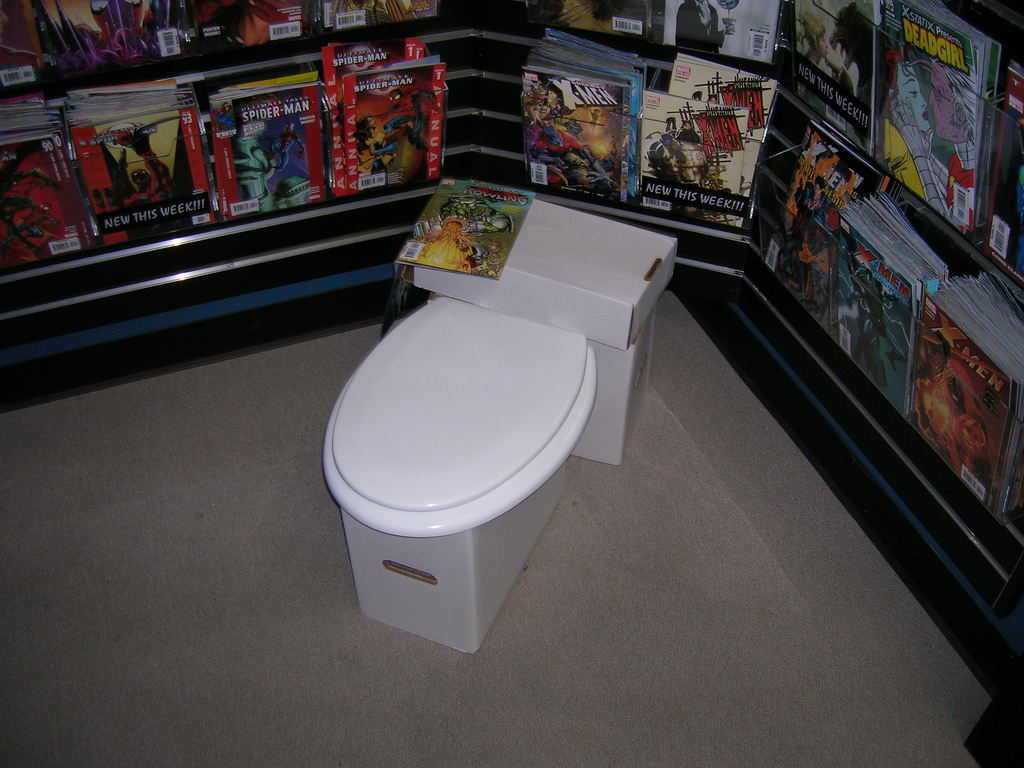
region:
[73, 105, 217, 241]
the colorful comic book on the shelf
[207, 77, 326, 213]
the colorful comic book on the shelf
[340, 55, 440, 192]
the colorful comic book on the shelf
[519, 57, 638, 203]
the colorful comic book on the shelf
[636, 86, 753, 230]
the colorful comic book on the shelf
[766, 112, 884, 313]
the colorful comic book on the shelf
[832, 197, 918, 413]
the colorful comic book on the shelf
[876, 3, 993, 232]
the colorful comic book on the shelf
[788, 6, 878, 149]
the colorful comic book on the shelf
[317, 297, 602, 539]
the toilet seat on the box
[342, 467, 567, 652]
the box under the toilet seat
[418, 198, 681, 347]
the lid of the box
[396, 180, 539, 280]
the magazine on the lid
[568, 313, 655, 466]
the box on the ground acting as the tank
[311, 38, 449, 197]
the spider man magazine behind the toilet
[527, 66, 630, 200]
the x-men magazine behind the lid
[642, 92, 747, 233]
the tan x men magazine behind the lid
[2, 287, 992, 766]
the floor under the boxes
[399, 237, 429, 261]
the white upc on the magazine lid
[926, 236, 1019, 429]
a magazine on the shelf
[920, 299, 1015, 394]
a magazine on the shelf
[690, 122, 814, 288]
a magazine on the shelf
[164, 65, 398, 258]
a magazine on the shelf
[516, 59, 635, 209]
multi colored comic with white lettering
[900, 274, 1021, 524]
orange and black cover to X-MEN comic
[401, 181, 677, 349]
white top of a cardboard box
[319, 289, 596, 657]
white porcelain toilet seat sitting on a box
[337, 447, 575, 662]
white cardboard box with a tan opening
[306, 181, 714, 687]
Makeshift toilet on floor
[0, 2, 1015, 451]
Comic books on wall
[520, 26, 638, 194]
Comics on a shelf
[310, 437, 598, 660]
White box under toilet seat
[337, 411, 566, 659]
Box under toilet seat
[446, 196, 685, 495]
Boxes near the wall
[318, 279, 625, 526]
Toilet seat above box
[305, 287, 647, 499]
White toilet seat above box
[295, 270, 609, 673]
the toilet has a lid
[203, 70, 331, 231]
magazines on display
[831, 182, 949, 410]
books on a pile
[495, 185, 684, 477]
the box is color white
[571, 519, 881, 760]
teh floor is gray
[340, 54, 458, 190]
A comic on a shelf.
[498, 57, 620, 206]
A comic on a shelf.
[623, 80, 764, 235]
A comic on a shelf.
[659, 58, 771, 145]
A comic on a shelf.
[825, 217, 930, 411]
A comic on a shelf.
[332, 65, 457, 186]
A comic on a shelf.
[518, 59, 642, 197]
A comic on a shelf.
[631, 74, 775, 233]
A comic on a shelf.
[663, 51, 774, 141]
A comic on a shelf.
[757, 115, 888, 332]
A comic on a shelf.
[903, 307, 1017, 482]
A comic on a shelf.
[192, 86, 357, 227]
A comic on a shelf.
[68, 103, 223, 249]
A comic on a shelf.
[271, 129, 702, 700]
a toilet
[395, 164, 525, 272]
a comic book on the toilet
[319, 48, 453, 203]
spiderman comic book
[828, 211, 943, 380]
x men comic book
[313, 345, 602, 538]
top of toilet lid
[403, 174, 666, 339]
a white box